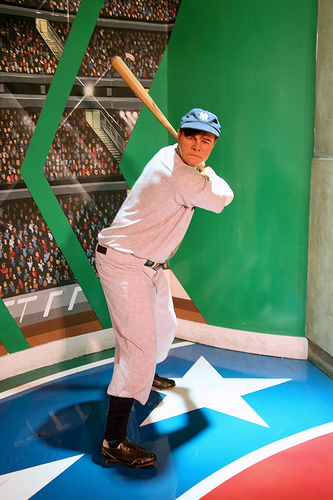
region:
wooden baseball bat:
[108, 54, 216, 172]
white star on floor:
[138, 349, 299, 431]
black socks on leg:
[98, 386, 136, 452]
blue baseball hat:
[174, 98, 228, 137]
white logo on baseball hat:
[196, 109, 213, 125]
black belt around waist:
[93, 240, 172, 269]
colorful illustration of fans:
[0, 0, 177, 307]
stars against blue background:
[1, 314, 327, 499]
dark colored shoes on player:
[94, 432, 163, 470]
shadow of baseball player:
[24, 358, 216, 477]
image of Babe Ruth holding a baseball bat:
[92, 54, 232, 468]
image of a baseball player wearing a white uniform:
[91, 49, 229, 466]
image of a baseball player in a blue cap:
[91, 53, 230, 468]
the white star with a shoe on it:
[137, 353, 289, 424]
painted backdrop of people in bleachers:
[0, 0, 177, 337]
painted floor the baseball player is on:
[0, 337, 329, 494]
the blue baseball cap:
[177, 105, 216, 131]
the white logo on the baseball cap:
[196, 107, 203, 114]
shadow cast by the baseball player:
[35, 378, 205, 478]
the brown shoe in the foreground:
[99, 437, 155, 467]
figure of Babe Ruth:
[95, 96, 238, 477]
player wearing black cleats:
[99, 441, 145, 475]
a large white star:
[162, 361, 251, 443]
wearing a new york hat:
[172, 105, 240, 139]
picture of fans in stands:
[0, 4, 136, 294]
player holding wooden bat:
[101, 54, 179, 145]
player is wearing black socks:
[106, 400, 127, 442]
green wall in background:
[210, 49, 313, 335]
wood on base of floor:
[0, 316, 99, 346]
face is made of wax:
[177, 126, 215, 172]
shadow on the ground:
[47, 384, 151, 471]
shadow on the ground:
[72, 369, 205, 485]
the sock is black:
[94, 383, 148, 467]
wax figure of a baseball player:
[83, 36, 280, 483]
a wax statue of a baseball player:
[57, 46, 299, 495]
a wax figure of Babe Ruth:
[36, 35, 298, 498]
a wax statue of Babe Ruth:
[34, 44, 276, 476]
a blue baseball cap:
[163, 98, 239, 136]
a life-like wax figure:
[76, 51, 311, 473]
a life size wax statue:
[65, 32, 276, 470]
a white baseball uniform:
[100, 137, 210, 410]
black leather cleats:
[76, 429, 180, 494]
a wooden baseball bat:
[107, 50, 180, 146]